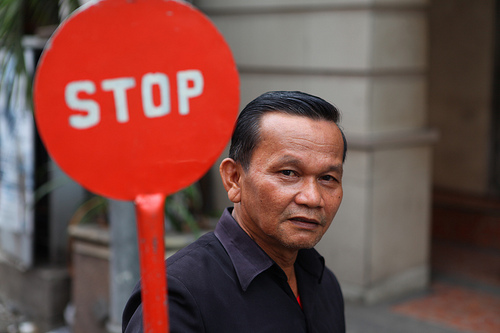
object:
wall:
[207, 0, 494, 298]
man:
[140, 91, 347, 332]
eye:
[317, 175, 339, 184]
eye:
[275, 170, 302, 179]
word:
[65, 70, 203, 131]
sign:
[35, 0, 239, 331]